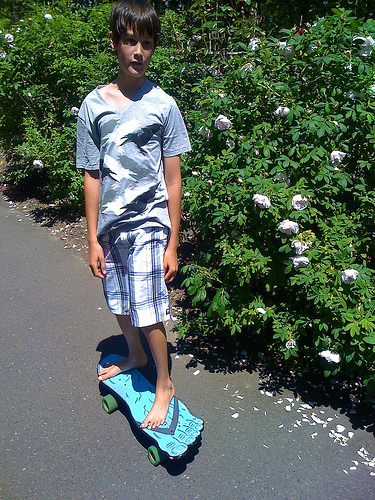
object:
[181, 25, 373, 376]
bush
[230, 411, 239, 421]
petals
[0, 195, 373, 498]
ground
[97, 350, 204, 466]
skateboard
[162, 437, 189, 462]
toes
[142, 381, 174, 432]
feet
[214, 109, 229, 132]
flower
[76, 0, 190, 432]
boy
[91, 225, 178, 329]
shorts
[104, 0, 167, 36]
hair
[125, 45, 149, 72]
facial expression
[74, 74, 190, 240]
shirt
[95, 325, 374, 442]
shadow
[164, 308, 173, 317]
logo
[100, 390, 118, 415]
tire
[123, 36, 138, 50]
eyes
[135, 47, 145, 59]
nose